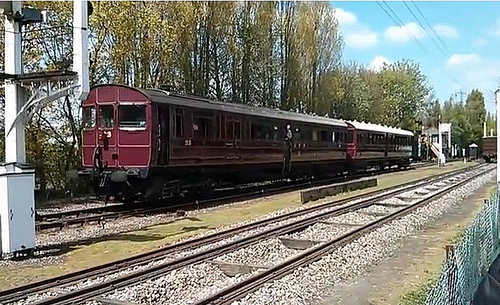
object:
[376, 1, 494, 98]
lines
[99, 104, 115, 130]
window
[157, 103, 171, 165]
entry door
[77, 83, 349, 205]
car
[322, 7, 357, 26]
cloud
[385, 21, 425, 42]
cloud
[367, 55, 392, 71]
cloud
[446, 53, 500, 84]
cloud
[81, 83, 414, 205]
train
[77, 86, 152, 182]
coupling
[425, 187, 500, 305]
fence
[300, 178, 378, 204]
rail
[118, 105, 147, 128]
window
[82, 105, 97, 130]
window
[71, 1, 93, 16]
light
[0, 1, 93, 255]
light train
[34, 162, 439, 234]
track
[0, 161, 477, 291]
strairway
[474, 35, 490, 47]
cloud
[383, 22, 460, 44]
cloud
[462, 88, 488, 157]
tree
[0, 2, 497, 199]
trees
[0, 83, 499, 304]
train bed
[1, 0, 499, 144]
clouds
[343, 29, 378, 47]
cloud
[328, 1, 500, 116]
blue sky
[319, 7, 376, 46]
cloud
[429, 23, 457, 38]
cloud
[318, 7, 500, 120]
clouds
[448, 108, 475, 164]
trees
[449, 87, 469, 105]
ferris wheel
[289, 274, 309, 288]
stones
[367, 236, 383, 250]
stones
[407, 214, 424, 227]
stones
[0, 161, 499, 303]
rail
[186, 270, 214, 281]
stones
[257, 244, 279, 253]
stones